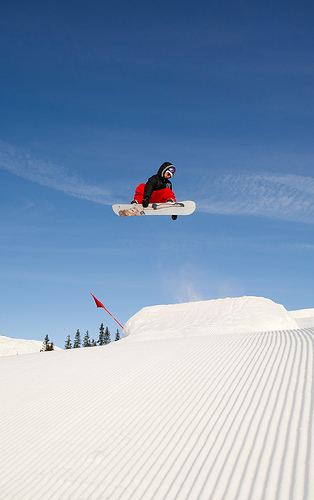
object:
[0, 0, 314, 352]
sky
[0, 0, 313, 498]
scene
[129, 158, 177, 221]
man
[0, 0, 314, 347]
air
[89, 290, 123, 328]
flag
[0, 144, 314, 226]
clouds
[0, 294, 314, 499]
snow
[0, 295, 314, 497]
side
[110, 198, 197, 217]
snowboard